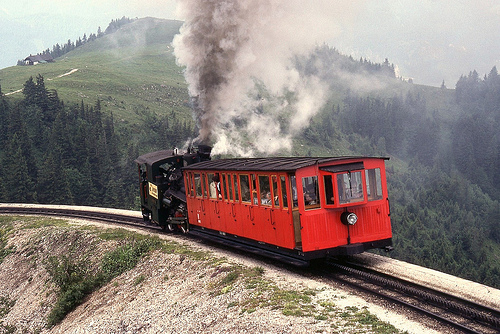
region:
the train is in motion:
[88, 107, 429, 269]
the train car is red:
[104, 106, 439, 282]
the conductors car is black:
[120, 125, 196, 232]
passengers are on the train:
[173, 128, 393, 242]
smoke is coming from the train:
[136, 22, 334, 162]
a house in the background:
[2, 12, 97, 89]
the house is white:
[7, 36, 67, 76]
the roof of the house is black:
[21, 52, 51, 63]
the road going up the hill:
[55, 48, 134, 88]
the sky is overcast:
[250, 4, 485, 99]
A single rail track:
[350, 276, 392, 281]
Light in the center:
[347, 216, 356, 221]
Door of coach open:
[293, 217, 298, 243]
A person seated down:
[304, 193, 315, 203]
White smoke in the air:
[226, 102, 236, 113]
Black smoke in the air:
[204, 76, 213, 86]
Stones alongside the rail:
[400, 306, 407, 313]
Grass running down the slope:
[62, 286, 77, 303]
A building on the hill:
[27, 56, 35, 63]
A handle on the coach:
[267, 208, 271, 220]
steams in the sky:
[181, 10, 323, 147]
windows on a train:
[326, 159, 366, 208]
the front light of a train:
[342, 205, 365, 229]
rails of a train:
[356, 261, 485, 329]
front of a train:
[295, 163, 406, 257]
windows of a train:
[196, 163, 290, 208]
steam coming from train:
[164, 34, 315, 147]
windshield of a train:
[332, 165, 368, 202]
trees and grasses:
[382, 85, 495, 162]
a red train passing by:
[141, 112, 416, 269]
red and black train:
[135, 136, 393, 264]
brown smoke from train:
[171, 15, 283, 105]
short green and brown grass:
[24, 246, 88, 278]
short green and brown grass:
[62, 258, 106, 280]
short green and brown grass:
[421, 162, 459, 199]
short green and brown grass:
[125, 72, 167, 106]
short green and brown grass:
[81, 59, 129, 103]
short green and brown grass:
[142, 286, 210, 330]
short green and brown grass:
[228, 285, 266, 323]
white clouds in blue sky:
[18, 16, 62, 43]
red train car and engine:
[131, 132, 398, 271]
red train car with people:
[178, 151, 397, 272]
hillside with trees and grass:
[11, 15, 133, 167]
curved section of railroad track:
[2, 193, 139, 241]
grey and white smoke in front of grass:
[171, 14, 299, 157]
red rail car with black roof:
[180, 152, 400, 267]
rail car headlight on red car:
[336, 207, 362, 228]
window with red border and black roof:
[318, 158, 372, 210]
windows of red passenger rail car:
[183, 168, 290, 213]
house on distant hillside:
[16, 50, 57, 68]